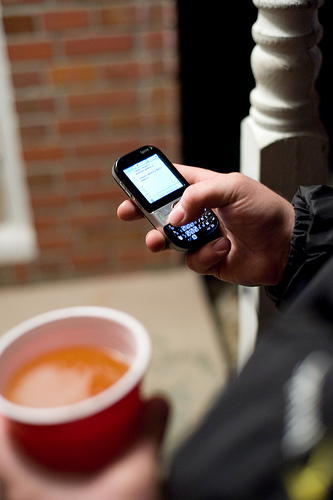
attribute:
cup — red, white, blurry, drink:
[0, 302, 151, 476]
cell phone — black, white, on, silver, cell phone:
[111, 143, 222, 254]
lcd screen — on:
[123, 153, 184, 204]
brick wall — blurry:
[0, 1, 187, 288]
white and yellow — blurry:
[283, 353, 330, 499]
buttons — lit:
[166, 208, 217, 246]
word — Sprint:
[139, 145, 151, 155]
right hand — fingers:
[117, 163, 295, 290]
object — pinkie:
[184, 237, 230, 273]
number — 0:
[190, 234, 197, 242]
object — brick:
[43, 9, 91, 32]